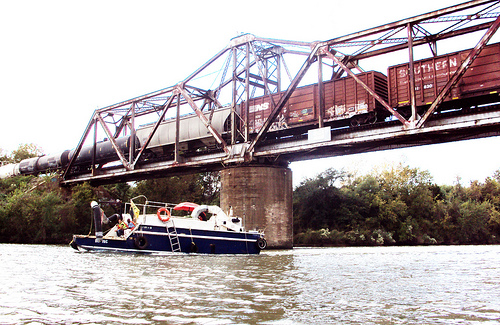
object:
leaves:
[358, 181, 414, 218]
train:
[0, 41, 499, 187]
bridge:
[58, 0, 500, 250]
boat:
[69, 201, 267, 255]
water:
[1, 244, 500, 323]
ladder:
[165, 218, 182, 253]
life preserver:
[156, 207, 172, 222]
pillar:
[219, 167, 296, 249]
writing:
[397, 58, 462, 78]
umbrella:
[174, 202, 202, 215]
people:
[115, 218, 136, 237]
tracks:
[59, 104, 500, 181]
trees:
[0, 144, 500, 245]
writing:
[94, 238, 108, 244]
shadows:
[89, 248, 295, 274]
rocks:
[0, 233, 500, 246]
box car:
[239, 70, 390, 142]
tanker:
[67, 135, 136, 172]